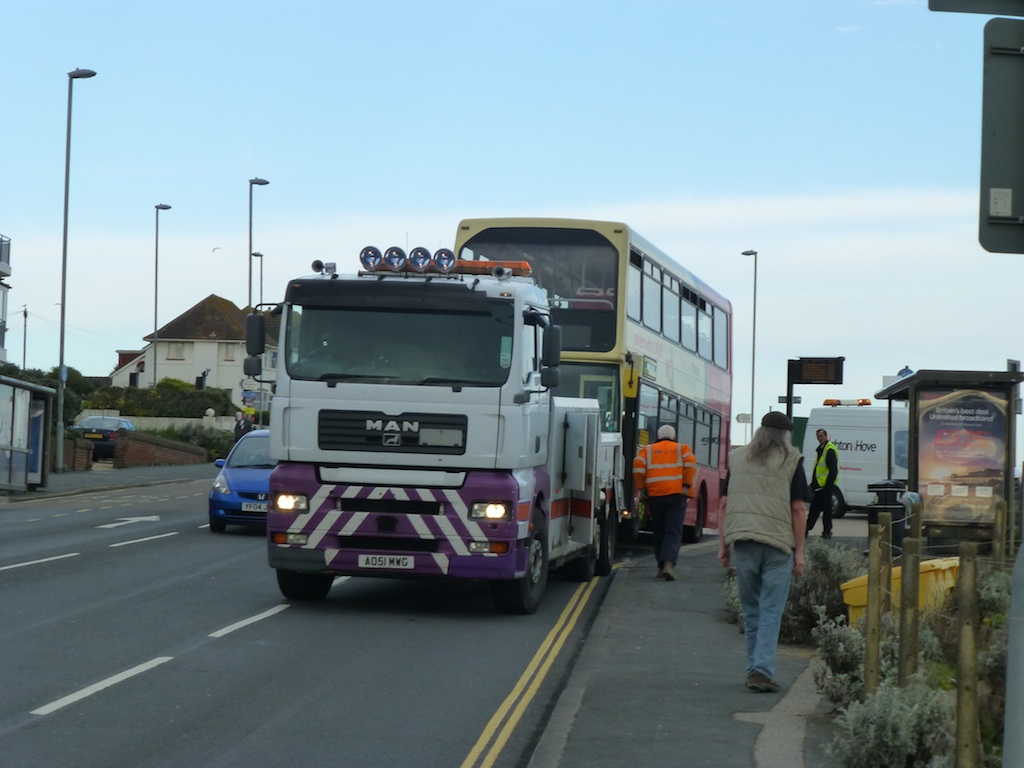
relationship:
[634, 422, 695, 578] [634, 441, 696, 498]
man in jacket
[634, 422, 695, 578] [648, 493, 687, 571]
man in pants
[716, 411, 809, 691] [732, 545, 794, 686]
man in jeans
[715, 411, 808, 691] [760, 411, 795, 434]
man wearing cap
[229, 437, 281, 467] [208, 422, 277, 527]
window on car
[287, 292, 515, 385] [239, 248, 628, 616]
window on bus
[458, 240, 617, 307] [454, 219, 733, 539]
window on bus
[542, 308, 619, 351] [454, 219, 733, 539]
window on bus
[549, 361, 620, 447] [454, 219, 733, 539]
window on bus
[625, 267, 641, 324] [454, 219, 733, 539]
window on bus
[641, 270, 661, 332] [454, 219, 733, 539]
window on bus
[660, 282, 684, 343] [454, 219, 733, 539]
window on bus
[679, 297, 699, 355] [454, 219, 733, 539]
window on bus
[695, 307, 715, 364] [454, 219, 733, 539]
window on bus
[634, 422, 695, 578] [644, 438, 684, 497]
man has vest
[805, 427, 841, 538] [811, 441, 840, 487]
man wears vest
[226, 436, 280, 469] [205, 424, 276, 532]
windshield on car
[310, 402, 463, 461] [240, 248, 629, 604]
grill on bus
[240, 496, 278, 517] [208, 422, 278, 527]
license plate on car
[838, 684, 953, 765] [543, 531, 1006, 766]
shrub on ground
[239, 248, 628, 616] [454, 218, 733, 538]
bus towing bus